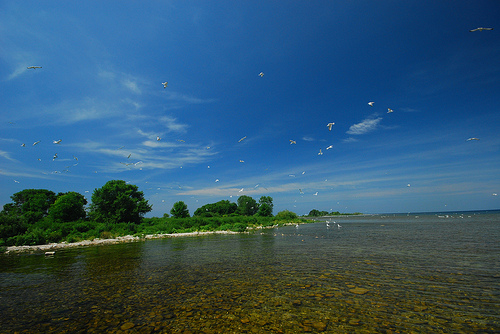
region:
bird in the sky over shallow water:
[387, 106, 393, 113]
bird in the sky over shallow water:
[364, 98, 375, 106]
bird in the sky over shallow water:
[325, 118, 336, 130]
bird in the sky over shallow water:
[237, 133, 247, 143]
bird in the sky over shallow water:
[49, 136, 60, 146]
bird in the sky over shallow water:
[48, 148, 59, 160]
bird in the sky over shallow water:
[26, 64, 43, 71]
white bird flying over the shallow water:
[365, 100, 376, 106]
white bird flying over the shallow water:
[384, 105, 396, 113]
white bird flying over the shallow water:
[470, 25, 494, 35]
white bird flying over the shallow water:
[325, 118, 336, 130]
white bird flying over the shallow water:
[286, 137, 298, 149]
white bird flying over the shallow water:
[257, 69, 266, 79]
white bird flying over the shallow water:
[159, 78, 170, 88]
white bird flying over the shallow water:
[50, 134, 61, 146]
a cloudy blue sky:
[1, 1, 498, 218]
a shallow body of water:
[2, 212, 499, 333]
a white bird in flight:
[161, 78, 168, 90]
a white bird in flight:
[153, 133, 162, 143]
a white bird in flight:
[25, 64, 43, 70]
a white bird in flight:
[257, 69, 265, 77]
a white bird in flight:
[51, 137, 60, 145]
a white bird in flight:
[31, 140, 38, 145]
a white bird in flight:
[287, 137, 296, 145]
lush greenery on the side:
[0, 117, 318, 260]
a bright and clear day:
[13, 11, 470, 326]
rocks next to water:
[13, 225, 251, 252]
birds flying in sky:
[15, 17, 472, 268]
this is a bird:
[308, 103, 353, 140]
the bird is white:
[313, 105, 355, 142]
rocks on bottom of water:
[154, 257, 429, 331]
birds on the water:
[268, 195, 422, 271]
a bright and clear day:
[3, 10, 490, 325]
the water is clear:
[126, 230, 403, 332]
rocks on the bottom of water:
[174, 246, 384, 331]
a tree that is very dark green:
[85, 177, 153, 232]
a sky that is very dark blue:
[185, 44, 462, 187]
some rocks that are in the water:
[234, 251, 365, 320]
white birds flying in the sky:
[17, 46, 499, 195]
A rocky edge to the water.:
[0, 220, 315, 252]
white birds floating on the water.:
[290, 211, 345, 227]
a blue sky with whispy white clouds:
[0, 1, 496, 216]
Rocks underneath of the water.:
[0, 225, 495, 330]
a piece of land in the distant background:
[300, 205, 371, 220]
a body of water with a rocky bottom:
[0, 205, 500, 330]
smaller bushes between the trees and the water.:
[0, 210, 320, 241]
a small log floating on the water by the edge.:
[41, 249, 56, 257]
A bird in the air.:
[325, 118, 337, 133]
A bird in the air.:
[366, 99, 373, 109]